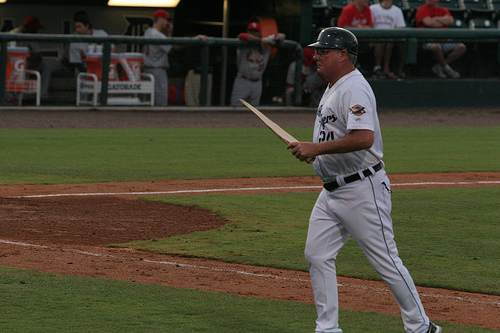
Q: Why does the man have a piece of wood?
A: Bat broke.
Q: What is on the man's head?
A: Helmet.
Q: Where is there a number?
A: Player's shirt.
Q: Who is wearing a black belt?
A: Player in helmet.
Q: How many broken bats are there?
A: 1.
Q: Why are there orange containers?
A: Drinks.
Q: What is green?
A: Grass on field.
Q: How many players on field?
A: 1.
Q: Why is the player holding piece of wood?
A: Bat broke.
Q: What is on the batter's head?
A: Helmet.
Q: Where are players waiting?
A: Dugout.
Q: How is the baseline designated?
A: White line in dirt.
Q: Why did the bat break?
A: Hit ball wrong.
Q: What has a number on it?
A: Player's shirt.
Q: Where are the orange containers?
A: Dugout.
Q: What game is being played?
A: Baseball.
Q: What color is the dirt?
A: Red.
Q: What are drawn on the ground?
A: White lines.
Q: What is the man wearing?
A: A baseball uniform.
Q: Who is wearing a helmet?
A: The baseball player.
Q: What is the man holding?
A: A broken bat.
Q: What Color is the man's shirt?
A: White.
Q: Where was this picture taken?
A: At a baseball game.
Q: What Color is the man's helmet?
A: Black.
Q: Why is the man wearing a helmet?
A: He plays baseball.